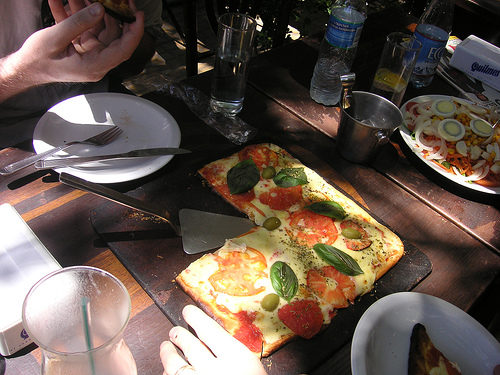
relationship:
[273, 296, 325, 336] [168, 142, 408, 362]
tomato slice on a pizza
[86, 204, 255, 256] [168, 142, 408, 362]
pie server under a pizza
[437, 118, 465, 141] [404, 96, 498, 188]
egg on a salad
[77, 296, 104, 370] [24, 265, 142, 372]
straw in a cup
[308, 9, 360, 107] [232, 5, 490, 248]
water bottle on a table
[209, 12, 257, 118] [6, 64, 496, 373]
glass on a table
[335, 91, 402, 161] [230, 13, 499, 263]
bucket on a table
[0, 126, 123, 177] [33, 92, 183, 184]
fork on a plate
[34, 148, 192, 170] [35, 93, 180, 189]
butter knife on a plate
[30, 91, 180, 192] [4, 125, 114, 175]
fork on a plate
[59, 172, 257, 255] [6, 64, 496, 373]
pie server on a table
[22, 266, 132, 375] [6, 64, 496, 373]
cup on a table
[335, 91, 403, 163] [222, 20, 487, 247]
bucket on a table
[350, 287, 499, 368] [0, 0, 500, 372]
plate on a table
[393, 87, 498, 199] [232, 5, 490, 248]
plate on a table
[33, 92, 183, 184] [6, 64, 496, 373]
plate on a table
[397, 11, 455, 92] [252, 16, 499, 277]
bottle on a table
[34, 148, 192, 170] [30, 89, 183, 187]
butter knife lying on top of plate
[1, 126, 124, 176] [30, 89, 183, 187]
utensil lying on top of plate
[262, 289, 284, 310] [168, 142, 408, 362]
olive on pizza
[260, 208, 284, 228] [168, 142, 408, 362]
olive on pizza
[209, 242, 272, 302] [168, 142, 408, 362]
tomato slice on pizza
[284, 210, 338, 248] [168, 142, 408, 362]
tomato on pizza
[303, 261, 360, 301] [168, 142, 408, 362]
tomato slice on pizza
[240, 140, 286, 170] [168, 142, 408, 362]
tomato slice on pizza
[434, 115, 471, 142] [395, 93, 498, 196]
egg on salad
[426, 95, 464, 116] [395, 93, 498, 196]
egg on salad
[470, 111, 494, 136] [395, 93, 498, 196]
egg on salad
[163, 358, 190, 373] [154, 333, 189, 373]
ring on finger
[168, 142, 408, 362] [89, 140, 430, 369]
pizza on plate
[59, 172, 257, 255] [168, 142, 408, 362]
pie server for serving pizza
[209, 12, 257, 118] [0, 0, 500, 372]
glass on table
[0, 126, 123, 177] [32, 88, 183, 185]
fork on table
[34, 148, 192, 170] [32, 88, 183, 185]
butter knife on table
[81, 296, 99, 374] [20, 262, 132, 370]
straw in glass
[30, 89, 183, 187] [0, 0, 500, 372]
plate on table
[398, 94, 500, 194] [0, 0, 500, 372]
plate on table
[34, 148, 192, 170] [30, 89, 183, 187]
butter knife on plate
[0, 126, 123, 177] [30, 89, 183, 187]
fork on plate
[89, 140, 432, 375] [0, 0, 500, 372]
plate sitting on table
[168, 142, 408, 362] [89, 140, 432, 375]
pizza on plate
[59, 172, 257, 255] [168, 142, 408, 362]
pie server next to pizza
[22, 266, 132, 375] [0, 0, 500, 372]
cup sitting on table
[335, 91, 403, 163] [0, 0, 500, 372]
bucket on table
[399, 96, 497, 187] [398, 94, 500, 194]
food on plate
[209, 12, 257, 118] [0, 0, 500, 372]
glass sitting on table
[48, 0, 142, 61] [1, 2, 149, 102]
food in hand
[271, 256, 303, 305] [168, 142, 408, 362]
leaf on pizza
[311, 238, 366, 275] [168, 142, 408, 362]
leaf on pizza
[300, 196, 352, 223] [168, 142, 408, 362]
leaf on pizza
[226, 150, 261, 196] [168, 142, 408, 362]
leaf on pizza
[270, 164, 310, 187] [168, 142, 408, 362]
leaf on pizza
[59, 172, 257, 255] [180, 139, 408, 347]
pie server for serving pizza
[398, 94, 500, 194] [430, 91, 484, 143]
plate with eggs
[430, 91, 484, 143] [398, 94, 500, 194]
eggs on plate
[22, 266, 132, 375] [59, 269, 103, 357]
cup with straw